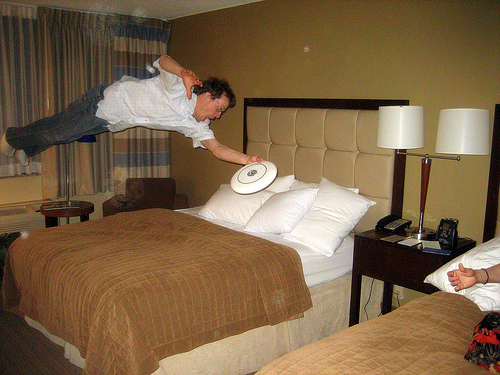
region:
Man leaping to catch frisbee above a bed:
[0, 55, 270, 166]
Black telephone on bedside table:
[371, 207, 409, 237]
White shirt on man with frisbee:
[97, 60, 217, 150]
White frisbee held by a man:
[225, 155, 280, 195]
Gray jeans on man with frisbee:
[2, 85, 107, 156]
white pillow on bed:
[280, 177, 360, 253]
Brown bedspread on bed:
[6, 206, 309, 372]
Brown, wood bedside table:
[345, 220, 475, 330]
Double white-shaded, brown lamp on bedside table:
[372, 101, 490, 246]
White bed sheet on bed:
[177, 205, 353, 285]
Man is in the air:
[6, 51, 271, 184]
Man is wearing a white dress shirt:
[84, 58, 226, 155]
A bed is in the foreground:
[3, 96, 416, 367]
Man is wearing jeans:
[8, 73, 120, 164]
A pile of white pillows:
[198, 165, 374, 251]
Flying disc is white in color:
[215, 147, 283, 209]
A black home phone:
[366, 197, 421, 247]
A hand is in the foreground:
[438, 251, 497, 310]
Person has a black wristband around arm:
[470, 262, 490, 295]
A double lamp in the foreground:
[370, 97, 496, 261]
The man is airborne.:
[4, 38, 279, 213]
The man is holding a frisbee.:
[2, 50, 282, 227]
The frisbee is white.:
[224, 150, 279, 196]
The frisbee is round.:
[226, 152, 281, 199]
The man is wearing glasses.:
[202, 88, 233, 123]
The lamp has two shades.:
[368, 89, 495, 248]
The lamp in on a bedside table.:
[342, 83, 498, 328]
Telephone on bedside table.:
[347, 87, 499, 336]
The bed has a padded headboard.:
[220, 87, 413, 319]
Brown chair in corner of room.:
[87, 144, 213, 236]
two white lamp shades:
[373, 102, 490, 167]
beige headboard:
[264, 110, 381, 153]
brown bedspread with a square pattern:
[48, 238, 250, 320]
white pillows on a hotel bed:
[204, 192, 327, 219]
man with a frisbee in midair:
[3, 61, 270, 191]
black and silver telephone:
[380, 212, 403, 232]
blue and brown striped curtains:
[114, 131, 164, 173]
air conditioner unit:
[1, 203, 34, 221]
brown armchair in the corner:
[143, 177, 182, 203]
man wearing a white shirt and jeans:
[86, 77, 220, 135]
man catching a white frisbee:
[20, 30, 296, 275]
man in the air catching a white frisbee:
[19, 32, 286, 207]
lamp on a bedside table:
[363, 72, 488, 259]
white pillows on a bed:
[224, 156, 379, 267]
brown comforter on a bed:
[34, 203, 288, 365]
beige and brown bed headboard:
[243, 87, 413, 213]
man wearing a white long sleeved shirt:
[12, 43, 277, 182]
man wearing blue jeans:
[14, 37, 293, 167]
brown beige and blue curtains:
[14, 2, 174, 107]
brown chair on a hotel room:
[101, 175, 196, 230]